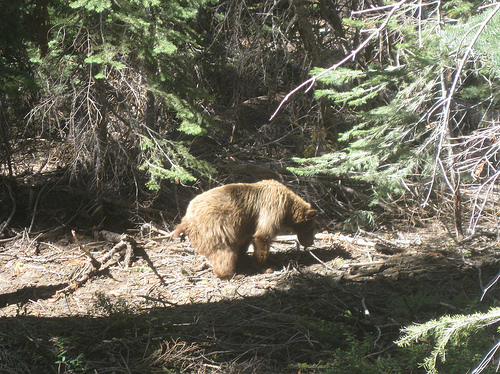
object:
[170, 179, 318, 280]
bear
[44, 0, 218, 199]
tree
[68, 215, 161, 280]
log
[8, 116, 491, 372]
ground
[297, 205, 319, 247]
head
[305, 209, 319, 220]
ears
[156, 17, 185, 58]
leaves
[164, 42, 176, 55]
cluster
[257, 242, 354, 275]
shadow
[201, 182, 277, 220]
back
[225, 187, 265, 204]
hump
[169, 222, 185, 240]
tail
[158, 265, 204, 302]
needles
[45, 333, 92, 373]
fern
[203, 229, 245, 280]
legs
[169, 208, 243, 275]
sit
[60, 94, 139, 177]
limbs